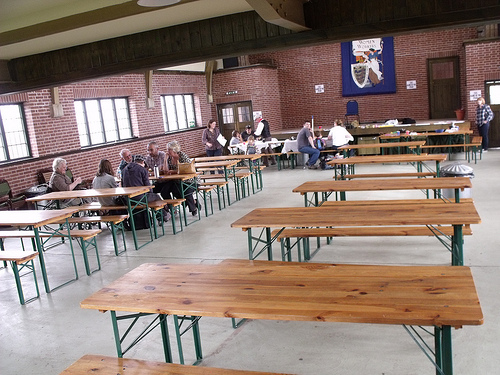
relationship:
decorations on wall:
[340, 34, 397, 98] [240, 21, 497, 161]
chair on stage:
[344, 98, 361, 125] [245, 61, 462, 186]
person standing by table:
[250, 109, 277, 169] [223, 133, 278, 153]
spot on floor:
[278, 350, 316, 365] [3, 126, 495, 370]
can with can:
[440, 163, 473, 199] [440, 162, 475, 179]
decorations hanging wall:
[331, 33, 405, 98] [208, 27, 498, 134]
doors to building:
[215, 102, 251, 134] [2, 1, 498, 216]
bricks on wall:
[278, 43, 341, 123] [248, 22, 483, 131]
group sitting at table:
[42, 139, 201, 232] [97, 247, 498, 354]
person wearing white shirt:
[326, 120, 355, 162] [328, 125, 355, 146]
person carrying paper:
[200, 112, 226, 150] [210, 117, 229, 160]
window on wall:
[1, 103, 33, 158] [0, 72, 213, 222]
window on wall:
[74, 95, 140, 150] [0, 72, 213, 222]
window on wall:
[164, 94, 178, 130] [0, 72, 213, 222]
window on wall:
[160, 90, 204, 134] [0, 72, 213, 222]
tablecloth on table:
[233, 135, 313, 152] [214, 135, 299, 170]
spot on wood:
[294, 281, 308, 291] [87, 260, 478, 315]